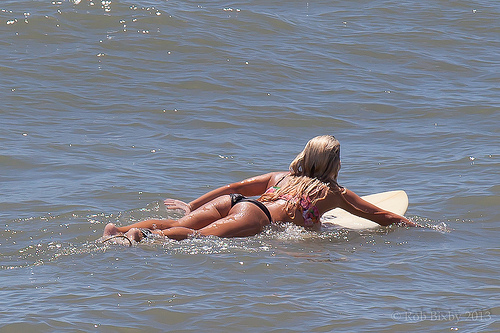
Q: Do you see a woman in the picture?
A: Yes, there is a woman.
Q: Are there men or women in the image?
A: Yes, there is a woman.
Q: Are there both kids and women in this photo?
A: No, there is a woman but no children.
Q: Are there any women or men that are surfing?
A: Yes, the woman is surfing.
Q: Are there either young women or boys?
A: Yes, there is a young woman.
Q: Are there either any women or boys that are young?
A: Yes, the woman is young.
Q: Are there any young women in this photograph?
A: Yes, there is a young woman.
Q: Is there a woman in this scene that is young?
A: Yes, there is a woman that is young.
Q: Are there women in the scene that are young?
A: Yes, there is a woman that is young.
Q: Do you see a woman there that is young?
A: Yes, there is a woman that is young.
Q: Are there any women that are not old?
A: Yes, there is an young woman.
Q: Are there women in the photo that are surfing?
A: Yes, there is a woman that is surfing.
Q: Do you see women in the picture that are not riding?
A: Yes, there is a woman that is surfing .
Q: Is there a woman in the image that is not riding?
A: Yes, there is a woman that is surfing.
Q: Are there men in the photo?
A: No, there are no men.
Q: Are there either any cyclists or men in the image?
A: No, there are no men or cyclists.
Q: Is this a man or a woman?
A: This is a woman.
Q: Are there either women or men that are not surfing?
A: No, there is a woman but she is surfing.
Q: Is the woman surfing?
A: Yes, the woman is surfing.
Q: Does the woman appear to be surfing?
A: Yes, the woman is surfing.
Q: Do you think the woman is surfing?
A: Yes, the woman is surfing.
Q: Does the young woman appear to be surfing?
A: Yes, the woman is surfing.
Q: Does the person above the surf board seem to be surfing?
A: Yes, the woman is surfing.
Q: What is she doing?
A: The woman is surfing.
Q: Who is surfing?
A: The woman is surfing.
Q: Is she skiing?
A: No, the woman is surfing.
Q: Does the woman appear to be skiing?
A: No, the woman is surfing.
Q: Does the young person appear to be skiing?
A: No, the woman is surfing.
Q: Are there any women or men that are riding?
A: No, there is a woman but she is surfing.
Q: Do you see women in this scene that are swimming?
A: No, there is a woman but she is surfing.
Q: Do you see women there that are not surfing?
A: No, there is a woman but she is surfing.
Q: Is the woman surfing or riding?
A: The woman is surfing.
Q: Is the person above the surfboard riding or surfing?
A: The woman is surfing.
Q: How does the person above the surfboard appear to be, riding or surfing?
A: The woman is surfing.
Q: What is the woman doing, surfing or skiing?
A: The woman is surfing.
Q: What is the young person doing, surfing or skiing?
A: The woman is surfing.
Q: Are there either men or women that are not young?
A: No, there is a woman but she is young.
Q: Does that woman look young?
A: Yes, the woman is young.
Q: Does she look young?
A: Yes, the woman is young.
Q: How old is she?
A: The woman is young.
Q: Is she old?
A: No, the woman is young.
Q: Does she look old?
A: No, the woman is young.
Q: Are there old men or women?
A: No, there is a woman but she is young.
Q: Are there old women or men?
A: No, there is a woman but she is young.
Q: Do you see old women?
A: No, there is a woman but she is young.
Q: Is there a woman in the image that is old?
A: No, there is a woman but she is young.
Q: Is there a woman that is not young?
A: No, there is a woman but she is young.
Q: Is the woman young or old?
A: The woman is young.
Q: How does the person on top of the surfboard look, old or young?
A: The woman is young.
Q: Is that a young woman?
A: Yes, that is a young woman.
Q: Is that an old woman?
A: No, that is a young woman.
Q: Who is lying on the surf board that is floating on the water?
A: The woman is lying on the surfboard.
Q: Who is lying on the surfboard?
A: The woman is lying on the surfboard.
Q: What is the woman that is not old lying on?
A: The woman is lying on the surfboard.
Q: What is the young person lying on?
A: The woman is lying on the surfboard.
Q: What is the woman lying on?
A: The woman is lying on the surfboard.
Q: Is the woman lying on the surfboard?
A: Yes, the woman is lying on the surfboard.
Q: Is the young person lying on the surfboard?
A: Yes, the woman is lying on the surfboard.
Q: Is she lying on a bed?
A: No, the woman is lying on the surfboard.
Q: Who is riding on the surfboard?
A: The woman is riding on the surfboard.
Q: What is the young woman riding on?
A: The woman is riding on the surfboard.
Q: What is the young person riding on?
A: The woman is riding on the surfboard.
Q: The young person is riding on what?
A: The woman is riding on the surfboard.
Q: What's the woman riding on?
A: The woman is riding on the surfboard.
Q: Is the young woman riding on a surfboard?
A: Yes, the woman is riding on a surfboard.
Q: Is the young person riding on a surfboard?
A: Yes, the woman is riding on a surfboard.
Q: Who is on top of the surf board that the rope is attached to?
A: The woman is on top of the surf board.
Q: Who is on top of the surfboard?
A: The woman is on top of the surf board.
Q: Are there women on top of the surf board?
A: Yes, there is a woman on top of the surf board.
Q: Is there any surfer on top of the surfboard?
A: No, there is a woman on top of the surfboard.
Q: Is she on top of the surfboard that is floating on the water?
A: Yes, the woman is on top of the surfboard.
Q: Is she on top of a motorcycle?
A: No, the woman is on top of the surfboard.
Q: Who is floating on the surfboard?
A: The woman is floating on the surfboard.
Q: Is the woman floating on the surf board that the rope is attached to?
A: Yes, the woman is floating on the surfboard.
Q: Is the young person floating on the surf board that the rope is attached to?
A: Yes, the woman is floating on the surfboard.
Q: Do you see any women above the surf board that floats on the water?
A: Yes, there is a woman above the surfboard.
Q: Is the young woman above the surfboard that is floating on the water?
A: Yes, the woman is above the surfboard.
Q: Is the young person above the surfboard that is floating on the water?
A: Yes, the woman is above the surfboard.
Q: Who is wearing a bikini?
A: The woman is wearing a bikini.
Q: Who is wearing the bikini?
A: The woman is wearing a bikini.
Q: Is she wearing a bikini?
A: Yes, the woman is wearing a bikini.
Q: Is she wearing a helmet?
A: No, the woman is wearing a bikini.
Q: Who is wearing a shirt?
A: The woman is wearing a shirt.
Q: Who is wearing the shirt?
A: The woman is wearing a shirt.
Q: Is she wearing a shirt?
A: Yes, the woman is wearing a shirt.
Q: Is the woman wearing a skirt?
A: No, the woman is wearing a shirt.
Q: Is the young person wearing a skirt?
A: No, the woman is wearing a shirt.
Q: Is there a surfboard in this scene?
A: Yes, there is a surfboard.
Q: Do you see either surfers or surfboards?
A: Yes, there is a surfboard.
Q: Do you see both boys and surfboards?
A: No, there is a surfboard but no boys.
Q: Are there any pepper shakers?
A: No, there are no pepper shakers.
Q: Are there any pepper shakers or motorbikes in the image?
A: No, there are no pepper shakers or motorbikes.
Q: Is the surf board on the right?
A: Yes, the surf board is on the right of the image.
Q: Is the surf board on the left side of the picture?
A: No, the surf board is on the right of the image.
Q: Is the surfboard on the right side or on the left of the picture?
A: The surfboard is on the right of the image.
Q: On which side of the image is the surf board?
A: The surf board is on the right of the image.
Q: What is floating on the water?
A: The surfboard is floating on the water.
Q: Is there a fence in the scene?
A: No, there are no fences.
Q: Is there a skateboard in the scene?
A: No, there are no skateboards.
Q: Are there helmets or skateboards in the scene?
A: No, there are no skateboards or helmets.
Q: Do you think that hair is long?
A: Yes, the hair is long.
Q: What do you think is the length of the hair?
A: The hair is long.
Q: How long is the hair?
A: The hair is long.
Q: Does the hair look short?
A: No, the hair is long.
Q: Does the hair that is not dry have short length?
A: No, the hair is long.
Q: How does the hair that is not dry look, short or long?
A: The hair is long.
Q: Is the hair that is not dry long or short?
A: The hair is long.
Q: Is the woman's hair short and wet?
A: No, the hair is wet but long.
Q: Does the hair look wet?
A: Yes, the hair is wet.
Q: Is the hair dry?
A: No, the hair is wet.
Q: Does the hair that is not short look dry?
A: No, the hair is wet.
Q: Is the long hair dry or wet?
A: The hair is wet.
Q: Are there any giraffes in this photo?
A: No, there are no giraffes.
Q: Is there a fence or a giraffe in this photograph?
A: No, there are no giraffes or fences.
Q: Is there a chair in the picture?
A: No, there are no chairs.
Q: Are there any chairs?
A: No, there are no chairs.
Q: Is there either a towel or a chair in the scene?
A: No, there are no chairs or towels.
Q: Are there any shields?
A: No, there are no shields.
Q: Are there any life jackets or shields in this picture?
A: No, there are no shields or life jackets.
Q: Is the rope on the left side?
A: Yes, the rope is on the left of the image.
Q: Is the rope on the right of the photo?
A: No, the rope is on the left of the image.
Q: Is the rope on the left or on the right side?
A: The rope is on the left of the image.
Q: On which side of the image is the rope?
A: The rope is on the left of the image.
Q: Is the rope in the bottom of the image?
A: Yes, the rope is in the bottom of the image.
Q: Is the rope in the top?
A: No, the rope is in the bottom of the image.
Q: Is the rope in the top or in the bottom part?
A: The rope is in the bottom of the image.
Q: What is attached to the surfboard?
A: The rope is attached to the surfboard.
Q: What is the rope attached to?
A: The rope is attached to the surfboard.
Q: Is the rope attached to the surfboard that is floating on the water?
A: Yes, the rope is attached to the surfboard.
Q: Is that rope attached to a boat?
A: No, the rope is attached to the surfboard.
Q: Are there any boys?
A: No, there are no boys.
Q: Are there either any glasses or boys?
A: No, there are no boys or glasses.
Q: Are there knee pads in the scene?
A: No, there are no knee pads.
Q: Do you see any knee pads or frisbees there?
A: No, there are no knee pads or frisbees.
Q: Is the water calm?
A: Yes, the water is calm.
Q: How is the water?
A: The water is calm.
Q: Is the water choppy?
A: No, the water is calm.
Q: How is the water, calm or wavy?
A: The water is calm.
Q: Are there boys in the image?
A: No, there are no boys.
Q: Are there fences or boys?
A: No, there are no boys or fences.